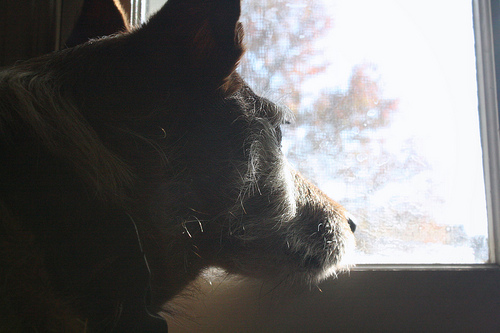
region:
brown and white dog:
[34, 0, 366, 290]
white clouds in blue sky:
[384, 51, 436, 89]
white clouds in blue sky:
[381, 131, 445, 182]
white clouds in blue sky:
[350, 188, 430, 240]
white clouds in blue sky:
[351, 65, 406, 113]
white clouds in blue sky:
[372, 23, 426, 67]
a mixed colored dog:
[3, 0, 363, 332]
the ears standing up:
[66, 3, 248, 79]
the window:
[141, 0, 491, 274]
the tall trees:
[147, 5, 434, 260]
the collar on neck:
[86, 33, 217, 277]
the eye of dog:
[264, 100, 292, 142]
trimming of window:
[127, 0, 499, 274]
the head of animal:
[63, 0, 358, 293]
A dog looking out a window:
[2, 0, 497, 330]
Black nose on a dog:
[337, 213, 360, 235]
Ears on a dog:
[62, 0, 262, 72]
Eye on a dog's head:
[265, 100, 285, 145]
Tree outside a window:
[252, 2, 396, 166]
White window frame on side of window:
[471, 3, 498, 264]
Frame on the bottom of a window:
[197, 261, 497, 331]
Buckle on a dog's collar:
[168, 212, 204, 243]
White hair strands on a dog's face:
[223, 139, 273, 207]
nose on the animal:
[342, 210, 358, 246]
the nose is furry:
[292, 180, 350, 269]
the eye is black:
[262, 117, 294, 158]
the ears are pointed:
[73, 5, 242, 73]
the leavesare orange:
[232, 5, 379, 133]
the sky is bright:
[341, 4, 486, 214]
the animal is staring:
[119, 10, 364, 258]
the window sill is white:
[188, 263, 483, 322]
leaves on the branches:
[282, 95, 394, 197]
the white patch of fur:
[232, 131, 288, 213]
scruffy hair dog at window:
[0, 0, 357, 331]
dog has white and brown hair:
[1, 1, 355, 330]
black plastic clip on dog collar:
[56, 211, 168, 331]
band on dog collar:
[0, 100, 122, 255]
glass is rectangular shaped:
[131, 0, 492, 270]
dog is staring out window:
[1, 2, 498, 332]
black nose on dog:
[346, 218, 357, 233]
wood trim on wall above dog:
[27, 1, 66, 61]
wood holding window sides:
[117, 0, 498, 266]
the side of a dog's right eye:
[275, 109, 290, 142]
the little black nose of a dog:
[344, 219, 354, 234]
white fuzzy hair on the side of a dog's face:
[195, 104, 341, 279]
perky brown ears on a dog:
[70, 0, 255, 79]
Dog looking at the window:
[1, 2, 498, 330]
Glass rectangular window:
[130, 0, 491, 269]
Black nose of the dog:
[346, 214, 358, 232]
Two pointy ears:
[61, 1, 248, 84]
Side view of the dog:
[3, 0, 362, 330]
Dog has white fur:
[2, 3, 362, 330]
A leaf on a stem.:
[398, 223, 404, 228]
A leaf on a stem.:
[353, 75, 358, 86]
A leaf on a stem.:
[291, 35, 293, 44]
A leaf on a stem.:
[316, 24, 326, 34]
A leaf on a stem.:
[296, 12, 303, 23]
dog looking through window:
[1, 2, 353, 330]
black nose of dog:
[345, 216, 357, 235]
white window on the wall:
[123, 0, 498, 292]